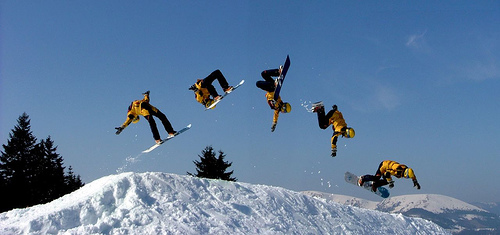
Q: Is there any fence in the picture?
A: No, there are no fences.